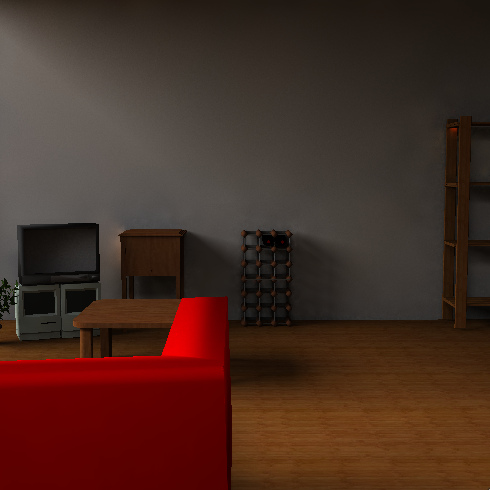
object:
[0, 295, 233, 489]
sofa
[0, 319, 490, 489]
tile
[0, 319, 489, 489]
floor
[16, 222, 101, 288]
television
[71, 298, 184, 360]
table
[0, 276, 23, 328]
plant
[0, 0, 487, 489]
living room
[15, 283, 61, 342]
monitor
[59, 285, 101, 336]
monitor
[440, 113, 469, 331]
edge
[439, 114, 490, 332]
stand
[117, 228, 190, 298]
table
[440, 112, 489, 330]
wooden shelf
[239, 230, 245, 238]
wooden ball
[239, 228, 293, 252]
shelf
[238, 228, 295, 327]
wine rack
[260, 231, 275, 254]
wine bottle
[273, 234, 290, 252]
wine bottle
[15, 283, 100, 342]
stand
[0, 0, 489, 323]
wall